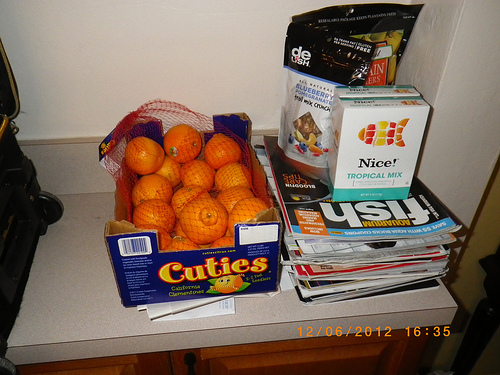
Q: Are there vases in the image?
A: No, there are no vases.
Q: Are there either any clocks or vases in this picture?
A: No, there are no vases or clocks.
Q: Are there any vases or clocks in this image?
A: No, there are no vases or clocks.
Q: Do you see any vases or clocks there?
A: No, there are no vases or clocks.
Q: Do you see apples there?
A: No, there are no apples.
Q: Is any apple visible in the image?
A: No, there are no apples.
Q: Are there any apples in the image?
A: No, there are no apples.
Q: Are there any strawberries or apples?
A: No, there are no apples or strawberries.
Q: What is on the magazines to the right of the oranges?
A: The nuts are on the magazines.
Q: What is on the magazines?
A: The nuts are on the magazines.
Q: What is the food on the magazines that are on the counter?
A: The food is nuts.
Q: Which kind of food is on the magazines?
A: The food is nuts.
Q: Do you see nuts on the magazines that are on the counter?
A: Yes, there are nuts on the magazines.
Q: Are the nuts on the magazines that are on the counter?
A: Yes, the nuts are on the magazines.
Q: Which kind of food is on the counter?
A: The food is nuts.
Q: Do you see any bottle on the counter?
A: No, there are nuts on the counter.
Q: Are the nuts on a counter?
A: Yes, the nuts are on a counter.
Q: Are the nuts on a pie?
A: No, the nuts are on a counter.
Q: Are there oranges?
A: Yes, there are oranges.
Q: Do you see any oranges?
A: Yes, there are oranges.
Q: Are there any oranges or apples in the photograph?
A: Yes, there are oranges.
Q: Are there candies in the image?
A: No, there are no candies.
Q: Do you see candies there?
A: No, there are no candies.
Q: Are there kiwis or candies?
A: No, there are no candies or kiwis.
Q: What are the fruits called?
A: The fruits are oranges.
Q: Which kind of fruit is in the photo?
A: The fruit is oranges.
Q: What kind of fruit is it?
A: The fruits are oranges.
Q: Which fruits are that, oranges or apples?
A: These are oranges.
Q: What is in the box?
A: The oranges are in the box.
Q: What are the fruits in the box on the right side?
A: The fruits are oranges.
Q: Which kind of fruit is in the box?
A: The fruits are oranges.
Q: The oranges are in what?
A: The oranges are in the box.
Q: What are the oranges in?
A: The oranges are in the box.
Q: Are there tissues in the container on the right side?
A: No, there are oranges in the box.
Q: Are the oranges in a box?
A: Yes, the oranges are in a box.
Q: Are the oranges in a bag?
A: No, the oranges are in a box.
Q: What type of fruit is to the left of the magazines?
A: The fruits are oranges.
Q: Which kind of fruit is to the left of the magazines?
A: The fruits are oranges.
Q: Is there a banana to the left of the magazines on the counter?
A: No, there are oranges to the left of the magazines.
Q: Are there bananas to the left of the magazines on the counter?
A: No, there are oranges to the left of the magazines.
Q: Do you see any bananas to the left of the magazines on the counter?
A: No, there are oranges to the left of the magazines.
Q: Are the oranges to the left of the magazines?
A: Yes, the oranges are to the left of the magazines.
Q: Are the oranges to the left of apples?
A: No, the oranges are to the left of the magazines.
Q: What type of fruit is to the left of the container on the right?
A: The fruits are oranges.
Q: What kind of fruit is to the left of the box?
A: The fruits are oranges.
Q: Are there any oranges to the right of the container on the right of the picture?
A: No, the oranges are to the left of the box.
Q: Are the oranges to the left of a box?
A: Yes, the oranges are to the left of a box.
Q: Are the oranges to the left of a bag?
A: No, the oranges are to the left of a box.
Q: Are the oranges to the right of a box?
A: No, the oranges are to the left of a box.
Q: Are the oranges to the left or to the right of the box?
A: The oranges are to the left of the box.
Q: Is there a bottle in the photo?
A: No, there are no bottles.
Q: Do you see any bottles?
A: No, there are no bottles.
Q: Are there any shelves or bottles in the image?
A: No, there are no bottles or shelves.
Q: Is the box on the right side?
A: Yes, the box is on the right of the image.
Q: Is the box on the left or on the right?
A: The box is on the right of the image.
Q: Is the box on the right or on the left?
A: The box is on the right of the image.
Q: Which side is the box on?
A: The box is on the right of the image.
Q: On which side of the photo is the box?
A: The box is on the right of the image.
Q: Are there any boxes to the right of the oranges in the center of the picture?
A: Yes, there is a box to the right of the oranges.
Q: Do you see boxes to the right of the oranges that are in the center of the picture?
A: Yes, there is a box to the right of the oranges.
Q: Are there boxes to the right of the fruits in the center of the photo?
A: Yes, there is a box to the right of the oranges.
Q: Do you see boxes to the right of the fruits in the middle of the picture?
A: Yes, there is a box to the right of the oranges.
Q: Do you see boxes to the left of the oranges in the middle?
A: No, the box is to the right of the oranges.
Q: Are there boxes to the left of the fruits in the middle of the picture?
A: No, the box is to the right of the oranges.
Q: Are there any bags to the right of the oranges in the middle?
A: No, there is a box to the right of the oranges.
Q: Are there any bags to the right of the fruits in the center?
A: No, there is a box to the right of the oranges.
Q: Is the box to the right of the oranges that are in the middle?
A: Yes, the box is to the right of the oranges.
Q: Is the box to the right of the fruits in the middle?
A: Yes, the box is to the right of the oranges.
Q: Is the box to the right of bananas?
A: No, the box is to the right of the oranges.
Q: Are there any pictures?
A: No, there are no pictures.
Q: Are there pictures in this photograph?
A: No, there are no pictures.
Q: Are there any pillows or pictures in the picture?
A: No, there are no pictures or pillows.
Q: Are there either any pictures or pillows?
A: No, there are no pictures or pillows.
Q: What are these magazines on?
A: The magazines are on the counter.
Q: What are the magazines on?
A: The magazines are on the counter.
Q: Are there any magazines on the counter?
A: Yes, there are magazines on the counter.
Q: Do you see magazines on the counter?
A: Yes, there are magazines on the counter.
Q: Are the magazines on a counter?
A: Yes, the magazines are on a counter.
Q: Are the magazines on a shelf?
A: No, the magazines are on a counter.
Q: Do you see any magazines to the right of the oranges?
A: Yes, there are magazines to the right of the oranges.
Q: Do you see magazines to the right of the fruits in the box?
A: Yes, there are magazines to the right of the oranges.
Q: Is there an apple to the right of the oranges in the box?
A: No, there are magazines to the right of the oranges.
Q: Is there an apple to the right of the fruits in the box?
A: No, there are magazines to the right of the oranges.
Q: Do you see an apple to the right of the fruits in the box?
A: No, there are magazines to the right of the oranges.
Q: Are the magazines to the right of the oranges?
A: Yes, the magazines are to the right of the oranges.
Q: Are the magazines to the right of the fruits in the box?
A: Yes, the magazines are to the right of the oranges.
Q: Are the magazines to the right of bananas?
A: No, the magazines are to the right of the oranges.